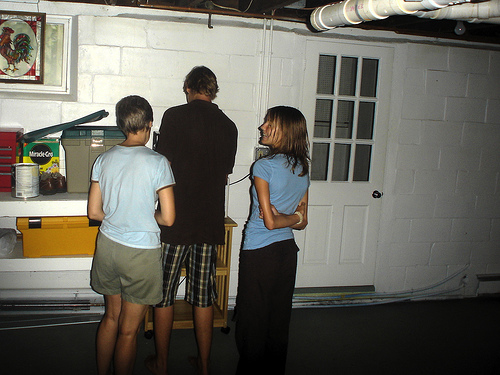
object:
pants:
[235, 235, 300, 374]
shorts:
[148, 238, 221, 309]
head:
[256, 104, 303, 146]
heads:
[114, 93, 157, 146]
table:
[0, 193, 88, 220]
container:
[60, 123, 133, 195]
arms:
[252, 167, 290, 233]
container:
[16, 216, 103, 257]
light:
[450, 22, 466, 37]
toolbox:
[0, 126, 27, 194]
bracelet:
[293, 211, 309, 227]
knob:
[372, 189, 385, 200]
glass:
[334, 101, 353, 141]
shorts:
[87, 232, 166, 306]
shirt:
[90, 143, 176, 251]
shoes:
[40, 173, 57, 197]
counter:
[0, 192, 89, 216]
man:
[145, 62, 241, 374]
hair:
[186, 64, 221, 96]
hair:
[259, 104, 314, 178]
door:
[287, 38, 394, 289]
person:
[86, 94, 178, 374]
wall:
[0, 0, 500, 304]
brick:
[423, 68, 471, 100]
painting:
[0, 8, 46, 86]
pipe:
[306, 0, 461, 33]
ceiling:
[130, 0, 500, 44]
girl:
[226, 104, 314, 374]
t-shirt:
[241, 150, 311, 250]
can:
[10, 162, 41, 198]